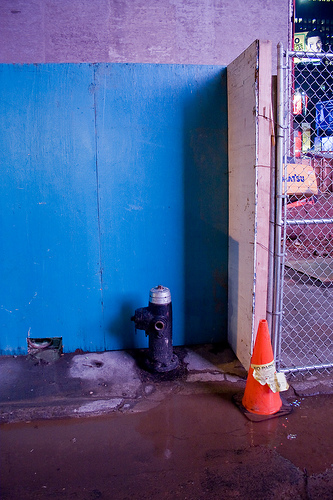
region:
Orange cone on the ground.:
[231, 316, 293, 424]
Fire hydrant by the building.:
[129, 282, 183, 381]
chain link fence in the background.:
[267, 39, 331, 378]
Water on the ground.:
[1, 381, 330, 499]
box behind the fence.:
[281, 161, 320, 198]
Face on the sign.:
[301, 33, 320, 56]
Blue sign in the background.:
[314, 98, 332, 127]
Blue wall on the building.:
[1, 60, 228, 353]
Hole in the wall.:
[23, 332, 67, 356]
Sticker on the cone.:
[249, 358, 291, 397]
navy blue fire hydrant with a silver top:
[130, 283, 189, 379]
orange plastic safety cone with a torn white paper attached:
[236, 317, 290, 424]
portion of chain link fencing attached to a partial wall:
[273, 40, 328, 371]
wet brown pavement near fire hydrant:
[2, 409, 321, 493]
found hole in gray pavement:
[67, 357, 110, 377]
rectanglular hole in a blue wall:
[18, 335, 68, 359]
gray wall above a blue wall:
[0, 0, 293, 59]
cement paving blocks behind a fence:
[280, 255, 328, 361]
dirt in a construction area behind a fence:
[278, 196, 326, 256]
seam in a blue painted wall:
[83, 60, 111, 348]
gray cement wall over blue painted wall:
[1, 0, 289, 64]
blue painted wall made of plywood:
[1, 61, 224, 354]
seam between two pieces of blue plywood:
[88, 61, 110, 350]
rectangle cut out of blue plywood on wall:
[19, 333, 70, 354]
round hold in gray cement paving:
[71, 357, 107, 377]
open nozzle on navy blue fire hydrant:
[150, 315, 168, 340]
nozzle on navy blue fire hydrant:
[127, 306, 151, 337]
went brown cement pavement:
[2, 410, 326, 497]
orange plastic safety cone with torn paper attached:
[240, 321, 293, 423]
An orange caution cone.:
[232, 316, 292, 420]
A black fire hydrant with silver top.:
[132, 284, 180, 372]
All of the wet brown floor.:
[2, 380, 329, 493]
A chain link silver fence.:
[271, 42, 331, 375]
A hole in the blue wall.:
[25, 334, 60, 354]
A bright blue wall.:
[0, 56, 226, 353]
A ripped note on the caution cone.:
[248, 359, 289, 394]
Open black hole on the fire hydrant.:
[153, 320, 165, 330]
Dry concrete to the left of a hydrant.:
[71, 352, 137, 381]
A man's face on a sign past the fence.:
[305, 30, 323, 54]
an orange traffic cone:
[232, 317, 291, 420]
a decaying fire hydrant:
[128, 283, 180, 374]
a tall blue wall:
[2, 63, 226, 353]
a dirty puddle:
[0, 383, 330, 484]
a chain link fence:
[277, 47, 331, 376]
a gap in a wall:
[21, 333, 64, 356]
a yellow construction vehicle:
[280, 165, 315, 194]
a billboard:
[290, 34, 325, 56]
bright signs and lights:
[292, 89, 331, 155]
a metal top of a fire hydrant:
[150, 281, 171, 304]